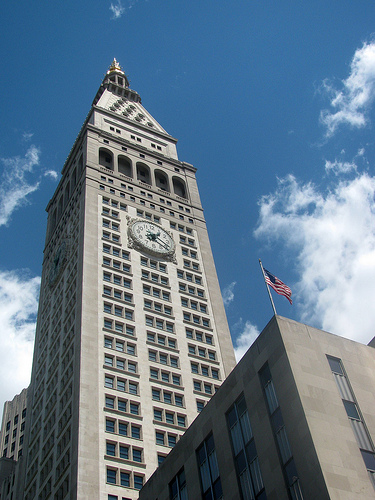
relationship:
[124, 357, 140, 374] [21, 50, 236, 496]
window on building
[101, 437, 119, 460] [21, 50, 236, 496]
window on building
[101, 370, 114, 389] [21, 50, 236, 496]
window on building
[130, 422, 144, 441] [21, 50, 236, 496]
window on building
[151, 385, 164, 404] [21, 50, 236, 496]
window on building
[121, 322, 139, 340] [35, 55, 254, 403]
window on building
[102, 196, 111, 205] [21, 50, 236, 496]
window on building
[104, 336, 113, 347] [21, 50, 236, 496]
window on building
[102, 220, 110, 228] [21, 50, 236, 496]
window on building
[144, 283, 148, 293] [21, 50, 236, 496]
window on building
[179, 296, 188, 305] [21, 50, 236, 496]
window on building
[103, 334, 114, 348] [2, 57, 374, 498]
window in building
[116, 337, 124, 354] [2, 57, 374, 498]
window in building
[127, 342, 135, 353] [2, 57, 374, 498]
window in building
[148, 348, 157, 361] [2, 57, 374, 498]
window in building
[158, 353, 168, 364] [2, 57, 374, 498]
window in building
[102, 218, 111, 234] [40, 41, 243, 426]
window on building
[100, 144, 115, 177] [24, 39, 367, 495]
window on building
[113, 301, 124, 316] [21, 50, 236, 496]
window on building